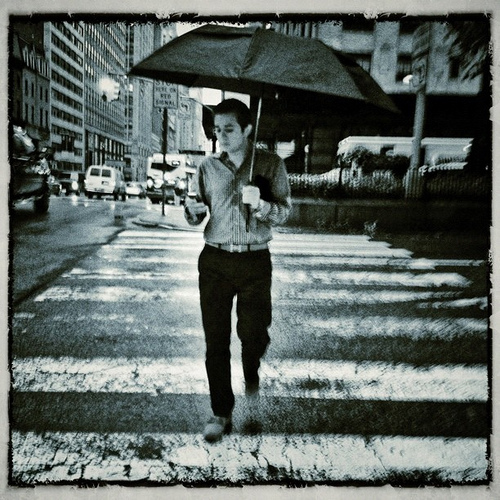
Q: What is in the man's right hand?
A: Cellphone.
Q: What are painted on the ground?
A: White lines.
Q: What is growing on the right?
A: A tree.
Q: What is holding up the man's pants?
A: Belt.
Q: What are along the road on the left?
A: Tall buildings.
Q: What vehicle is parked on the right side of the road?
A: City bus.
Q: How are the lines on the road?
A: White.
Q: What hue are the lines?
A: White.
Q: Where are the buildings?
A: On the side of the street.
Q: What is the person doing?
A: Walking.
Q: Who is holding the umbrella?
A: The man.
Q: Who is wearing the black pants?
A: The man.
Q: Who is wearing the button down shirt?
A: The man.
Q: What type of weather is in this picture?
A: Rainy.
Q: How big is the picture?
A: Large.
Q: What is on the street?
A: White painted lines.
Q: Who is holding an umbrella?
A: A man.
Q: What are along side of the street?
A: Buildings.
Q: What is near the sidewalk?
A: Black fence.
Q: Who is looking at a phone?
A: A man.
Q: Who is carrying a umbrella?
A: A man.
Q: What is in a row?
A: Buildings.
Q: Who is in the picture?
A: A man.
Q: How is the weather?
A: Rainy.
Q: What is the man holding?
A: An umbrella.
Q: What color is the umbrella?
A: Black.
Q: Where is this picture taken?
A: A street crossing.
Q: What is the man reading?
A: A phone.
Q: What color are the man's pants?
A: Black.